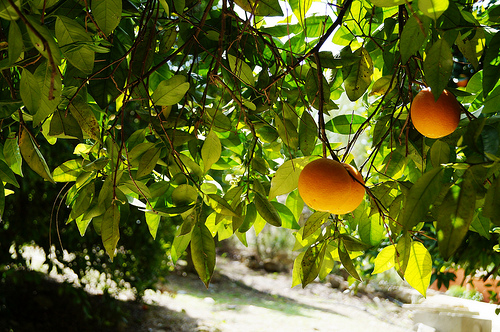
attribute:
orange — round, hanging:
[298, 154, 377, 221]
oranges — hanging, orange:
[273, 65, 497, 210]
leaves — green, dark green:
[23, 10, 257, 173]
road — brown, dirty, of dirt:
[182, 279, 379, 331]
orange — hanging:
[412, 81, 466, 138]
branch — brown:
[242, 10, 365, 148]